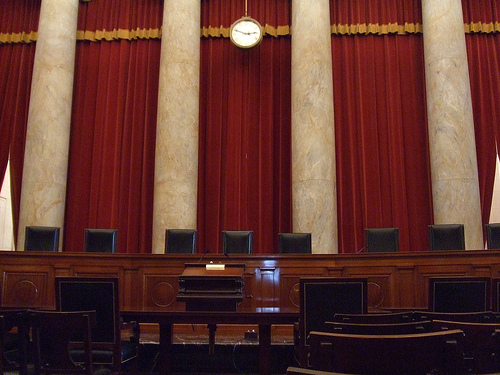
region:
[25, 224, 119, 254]
Two black chairs behind a large desk on the left.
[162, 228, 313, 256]
Three middle black chairs behind a large desk.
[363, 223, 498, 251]
First three black chairs to the right behind a desk.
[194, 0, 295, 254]
Middle red and gold curtain behind a clock.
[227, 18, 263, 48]
Clock face hanging in front of a curtain.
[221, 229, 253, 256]
Middle most black chair behind a long desk.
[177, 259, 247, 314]
Wooden speaker podium.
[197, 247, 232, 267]
Two microphones coming off a podium.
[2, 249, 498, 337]
Long wooden desk with many black chairs sitting at it.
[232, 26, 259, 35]
Black hands on a white clock.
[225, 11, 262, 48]
this is a clock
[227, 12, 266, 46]
the clock is above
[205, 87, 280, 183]
this is a curtain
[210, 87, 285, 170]
the curtain is red in color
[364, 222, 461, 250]
these are two chairs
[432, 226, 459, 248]
the chair is black in color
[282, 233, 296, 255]
the chair is empty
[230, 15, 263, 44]
the clock is white in color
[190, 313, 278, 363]
the stand is wooden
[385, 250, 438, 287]
the table is wooden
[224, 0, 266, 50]
hanging brown and white clock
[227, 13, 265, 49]
brown and white clock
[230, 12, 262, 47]
round clock with tan hands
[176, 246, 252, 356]
white paper on a wooden stand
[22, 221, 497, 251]
row of black seats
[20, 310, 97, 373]
brown wooden chair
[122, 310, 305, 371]
brown wooden table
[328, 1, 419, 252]
red and yellow curtain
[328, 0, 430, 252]
long red curtain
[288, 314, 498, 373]
group of brown seats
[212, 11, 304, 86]
a clock is hanging from ceiling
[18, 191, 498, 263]
8 chairs are behind the desk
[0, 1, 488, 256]
the curtains are red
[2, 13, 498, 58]
the curtains have gold trim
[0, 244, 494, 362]
the desks are made of wood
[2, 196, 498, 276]
the chairs are empty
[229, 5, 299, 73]
the time says 2:50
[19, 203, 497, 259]
the chairs are black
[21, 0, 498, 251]
the columns are made of stone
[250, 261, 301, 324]
light is reflecting off the wood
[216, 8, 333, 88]
Clock in the center of the room.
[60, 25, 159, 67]
Gold edging on red curtain.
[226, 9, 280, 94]
2 dark hands on clock.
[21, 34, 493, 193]
Large red curtain hanging on wall.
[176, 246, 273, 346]
Wood podium for speakers.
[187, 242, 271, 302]
Microphones attached to podium.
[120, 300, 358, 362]
Wood table in front of chairs.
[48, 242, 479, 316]
Long wood desk in front facing crowd.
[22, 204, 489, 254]
Tall back chairs behind wood desk.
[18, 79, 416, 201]
Tall pillars in front of curtain.